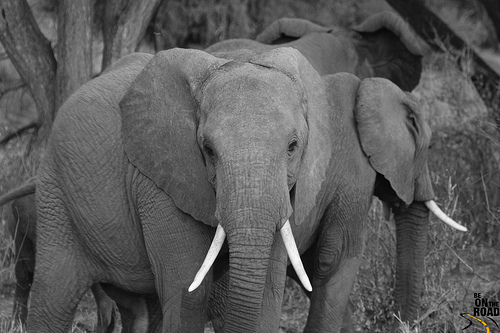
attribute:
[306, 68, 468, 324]
elephant —   in wild,  African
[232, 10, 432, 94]
elephant —  in wild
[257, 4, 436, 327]
elephant —  three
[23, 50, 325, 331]
elephant —  in wild,   African,   in wild,  African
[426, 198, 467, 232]
tusk —  two ,  long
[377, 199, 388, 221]
tusk —  long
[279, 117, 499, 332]
grass —  ground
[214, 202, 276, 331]
trunk —  wide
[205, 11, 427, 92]
elephant —  in herd,  African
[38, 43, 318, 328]
elephant —  forward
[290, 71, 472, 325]
elephant —   in wild,  African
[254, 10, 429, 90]
elephant —   in wild,  African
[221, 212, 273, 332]
trunk —  elephant's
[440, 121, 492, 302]
grass — tall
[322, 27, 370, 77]
head —  elephant's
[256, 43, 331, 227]
elephant's ear — african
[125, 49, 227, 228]
elephant's ear — african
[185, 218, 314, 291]
tusks —  elephant's,  white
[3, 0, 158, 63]
trunks —  of tree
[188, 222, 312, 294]
tusks —  white, of  elephant 